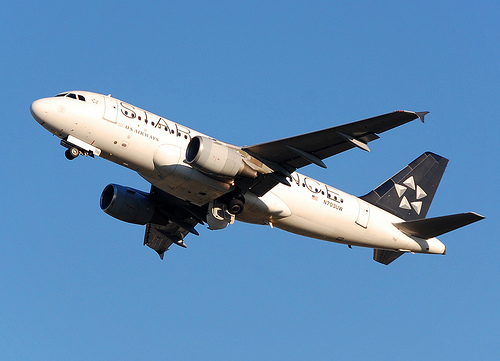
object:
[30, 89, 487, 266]
plane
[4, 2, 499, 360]
sky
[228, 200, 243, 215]
wheel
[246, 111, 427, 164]
wing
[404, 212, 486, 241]
back wing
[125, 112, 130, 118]
window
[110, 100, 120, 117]
door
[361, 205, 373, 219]
backdoor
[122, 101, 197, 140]
logo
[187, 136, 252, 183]
engine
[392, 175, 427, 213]
logo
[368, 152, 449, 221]
tail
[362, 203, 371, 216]
door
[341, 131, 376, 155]
slat